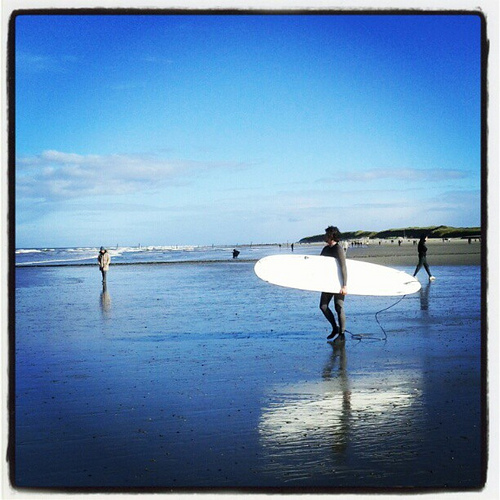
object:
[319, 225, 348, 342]
surfer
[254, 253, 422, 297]
surfboard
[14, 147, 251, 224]
cloud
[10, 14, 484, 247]
sky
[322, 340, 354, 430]
reflection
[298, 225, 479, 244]
mountain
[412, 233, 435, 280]
person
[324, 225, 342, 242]
hair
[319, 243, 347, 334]
wetsuit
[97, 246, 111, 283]
person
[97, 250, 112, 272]
jacket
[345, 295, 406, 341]
rope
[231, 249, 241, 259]
woman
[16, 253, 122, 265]
waves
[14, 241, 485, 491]
ocean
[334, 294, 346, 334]
legs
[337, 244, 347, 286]
arm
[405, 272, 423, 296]
end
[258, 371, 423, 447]
reflection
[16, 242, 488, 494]
water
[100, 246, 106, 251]
hat